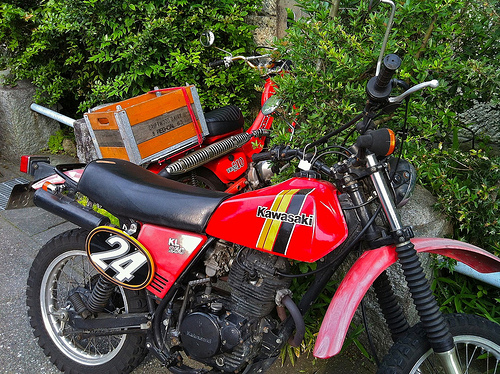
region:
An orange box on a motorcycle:
[87, 82, 200, 162]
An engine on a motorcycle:
[150, 248, 291, 367]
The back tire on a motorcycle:
[22, 228, 149, 370]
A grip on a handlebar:
[370, 51, 400, 98]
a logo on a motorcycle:
[253, 203, 315, 228]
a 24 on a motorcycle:
[90, 234, 147, 284]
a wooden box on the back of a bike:
[88, 83, 208, 165]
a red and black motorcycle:
[6, 55, 499, 372]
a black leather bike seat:
[76, 154, 237, 236]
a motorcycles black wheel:
[24, 228, 148, 372]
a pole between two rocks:
[25, 96, 77, 135]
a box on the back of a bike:
[84, 81, 214, 169]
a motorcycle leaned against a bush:
[0, 1, 495, 372]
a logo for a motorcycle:
[248, 197, 320, 239]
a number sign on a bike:
[83, 221, 156, 297]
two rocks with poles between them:
[0, 81, 102, 169]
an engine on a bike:
[177, 248, 307, 372]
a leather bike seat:
[72, 152, 239, 241]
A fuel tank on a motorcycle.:
[205, 171, 353, 266]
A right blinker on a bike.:
[355, 122, 400, 157]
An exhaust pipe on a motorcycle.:
[30, 183, 109, 231]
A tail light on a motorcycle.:
[16, 151, 47, 186]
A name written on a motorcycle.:
[251, 200, 320, 240]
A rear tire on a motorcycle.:
[26, 226, 151, 368]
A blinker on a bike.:
[356, 123, 403, 165]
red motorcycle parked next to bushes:
[3, 48, 495, 369]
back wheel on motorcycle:
[7, 225, 157, 371]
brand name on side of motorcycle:
[250, 200, 317, 236]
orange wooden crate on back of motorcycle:
[77, 77, 207, 167]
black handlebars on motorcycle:
[245, 41, 408, 172]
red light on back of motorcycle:
[12, 150, 38, 175]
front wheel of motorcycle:
[370, 305, 497, 370]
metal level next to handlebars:
[382, 71, 443, 109]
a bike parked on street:
[260, 133, 442, 368]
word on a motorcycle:
[251, 200, 330, 230]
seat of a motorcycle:
[74, 149, 215, 227]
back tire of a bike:
[21, 234, 155, 371]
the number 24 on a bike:
[89, 236, 146, 282]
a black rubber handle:
[365, 52, 402, 100]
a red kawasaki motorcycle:
[5, 56, 496, 371]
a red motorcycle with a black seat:
[3, 54, 498, 372]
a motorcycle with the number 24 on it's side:
[0, 54, 498, 371]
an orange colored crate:
[84, 83, 212, 165]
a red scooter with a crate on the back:
[83, 32, 326, 199]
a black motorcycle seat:
[78, 147, 231, 239]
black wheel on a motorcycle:
[21, 227, 156, 372]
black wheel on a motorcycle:
[377, 313, 499, 371]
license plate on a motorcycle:
[5, 183, 42, 211]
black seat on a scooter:
[199, 103, 243, 133]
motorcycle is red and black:
[5, 0, 499, 372]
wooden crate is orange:
[82, 83, 208, 165]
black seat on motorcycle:
[1, 0, 498, 372]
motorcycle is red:
[144, 26, 304, 195]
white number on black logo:
[84, 222, 156, 289]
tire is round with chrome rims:
[25, 227, 155, 372]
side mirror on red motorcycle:
[142, 28, 309, 205]